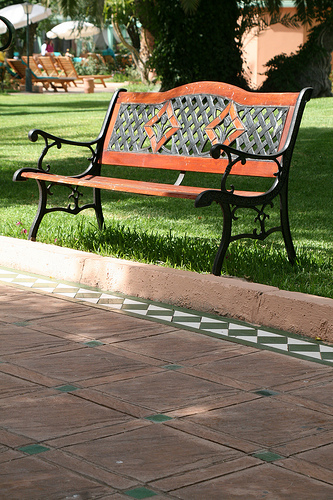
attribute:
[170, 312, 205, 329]
tile — green, diamond, colored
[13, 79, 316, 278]
bench — wood, black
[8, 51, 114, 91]
chairs — wooden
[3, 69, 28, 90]
plant — green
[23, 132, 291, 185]
armrests — black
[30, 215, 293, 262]
legs — black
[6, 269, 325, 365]
border — white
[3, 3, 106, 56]
two umbrellas — white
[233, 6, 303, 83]
building — peach colored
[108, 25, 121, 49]
sun — shining